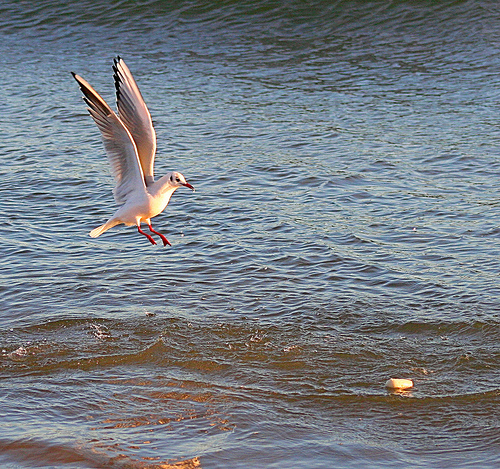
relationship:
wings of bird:
[71, 56, 158, 184] [68, 53, 194, 245]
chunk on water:
[386, 377, 414, 389] [0, 1, 498, 464]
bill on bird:
[182, 182, 194, 191] [68, 53, 194, 245]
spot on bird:
[168, 175, 171, 183] [68, 53, 194, 245]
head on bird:
[168, 171, 194, 189] [68, 53, 194, 245]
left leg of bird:
[143, 219, 163, 237] [68, 53, 194, 245]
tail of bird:
[88, 216, 118, 236] [68, 53, 194, 245]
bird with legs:
[68, 53, 194, 245] [135, 227, 169, 246]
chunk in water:
[383, 374, 413, 391] [0, 1, 498, 464]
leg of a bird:
[132, 227, 155, 247] [68, 53, 194, 245]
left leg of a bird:
[147, 225, 171, 245] [68, 53, 194, 245]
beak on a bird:
[182, 180, 193, 190] [68, 53, 194, 245]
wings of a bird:
[68, 50, 158, 206] [68, 53, 194, 245]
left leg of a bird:
[143, 219, 163, 237] [68, 53, 194, 245]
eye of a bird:
[173, 177, 181, 181] [68, 53, 194, 245]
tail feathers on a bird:
[88, 220, 117, 236] [68, 53, 194, 245]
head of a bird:
[165, 170, 195, 189] [68, 53, 194, 245]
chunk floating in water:
[386, 377, 414, 389] [0, 1, 498, 464]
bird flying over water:
[71, 56, 194, 246] [0, 1, 498, 464]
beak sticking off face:
[182, 183, 195, 190] [166, 162, 189, 200]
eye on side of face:
[176, 179, 180, 182] [162, 164, 192, 194]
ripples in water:
[205, 291, 312, 354] [24, 269, 469, 456]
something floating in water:
[369, 366, 429, 405] [312, 270, 459, 377]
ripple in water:
[348, 326, 498, 381] [0, 1, 498, 464]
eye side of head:
[176, 179, 180, 182] [162, 167, 191, 193]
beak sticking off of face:
[182, 183, 195, 190] [169, 170, 189, 190]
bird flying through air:
[71, 56, 194, 246] [178, 204, 222, 233]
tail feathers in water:
[88, 220, 117, 236] [173, 88, 467, 364]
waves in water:
[24, 314, 252, 378] [23, 8, 469, 450]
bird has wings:
[71, 56, 194, 246] [71, 71, 146, 207]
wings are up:
[71, 71, 146, 207] [74, 43, 140, 94]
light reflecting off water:
[75, 400, 235, 466] [54, 260, 358, 460]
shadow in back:
[14, 1, 498, 93] [7, 8, 495, 136]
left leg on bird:
[143, 219, 163, 237] [55, 40, 196, 253]